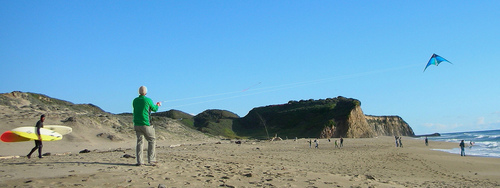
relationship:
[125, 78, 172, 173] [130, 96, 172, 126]
man wearing shirt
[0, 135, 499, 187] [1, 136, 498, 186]
beach in sand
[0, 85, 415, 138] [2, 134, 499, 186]
hills surround beach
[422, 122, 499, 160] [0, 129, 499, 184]
waves breaking into beach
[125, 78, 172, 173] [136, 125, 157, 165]
man wears pants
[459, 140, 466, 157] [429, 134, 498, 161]
man on shore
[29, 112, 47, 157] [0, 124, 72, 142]
surfer carries carrying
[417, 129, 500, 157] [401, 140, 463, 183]
waves on shore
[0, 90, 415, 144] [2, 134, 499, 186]
cliffs above beach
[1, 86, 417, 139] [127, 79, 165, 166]
cliffs beyond man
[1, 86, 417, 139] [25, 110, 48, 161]
cliffs beyond man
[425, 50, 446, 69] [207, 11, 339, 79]
kite in sky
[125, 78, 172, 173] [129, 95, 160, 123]
man wearing green shirt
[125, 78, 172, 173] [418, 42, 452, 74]
man flying kite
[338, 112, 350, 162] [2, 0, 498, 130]
ground flying in sky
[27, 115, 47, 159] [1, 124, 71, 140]
man carrying surf board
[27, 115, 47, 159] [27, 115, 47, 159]
man in man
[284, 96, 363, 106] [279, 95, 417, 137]
grass on cliff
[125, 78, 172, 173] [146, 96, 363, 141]
man wearing grass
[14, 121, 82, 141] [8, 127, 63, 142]
carrying two surfboard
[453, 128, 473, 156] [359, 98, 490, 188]
man standing near foamy water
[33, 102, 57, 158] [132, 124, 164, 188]
man flying kite wearing khaki pants